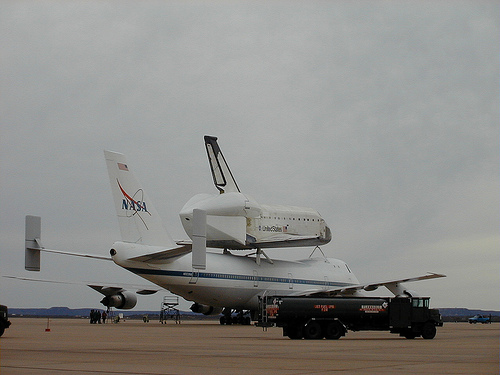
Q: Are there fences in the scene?
A: No, there are no fences.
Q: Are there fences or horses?
A: No, there are no fences or horses.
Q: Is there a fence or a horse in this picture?
A: No, there are no fences or horses.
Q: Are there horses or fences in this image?
A: No, there are no fences or horses.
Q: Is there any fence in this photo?
A: No, there are no fences.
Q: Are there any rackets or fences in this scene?
A: No, there are no fences or rackets.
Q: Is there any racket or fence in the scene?
A: No, there are no fences or rackets.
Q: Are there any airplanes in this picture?
A: Yes, there is an airplane.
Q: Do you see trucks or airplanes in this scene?
A: Yes, there is an airplane.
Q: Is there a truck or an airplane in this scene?
A: Yes, there is an airplane.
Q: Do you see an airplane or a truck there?
A: Yes, there is an airplane.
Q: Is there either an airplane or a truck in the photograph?
A: Yes, there is an airplane.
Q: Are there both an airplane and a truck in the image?
A: Yes, there are both an airplane and a truck.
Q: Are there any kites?
A: No, there are no kites.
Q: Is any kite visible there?
A: No, there are no kites.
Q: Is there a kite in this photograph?
A: No, there are no kites.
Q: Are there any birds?
A: No, there are no birds.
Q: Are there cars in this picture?
A: No, there are no cars.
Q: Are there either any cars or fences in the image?
A: No, there are no cars or fences.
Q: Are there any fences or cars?
A: No, there are no cars or fences.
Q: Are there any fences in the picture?
A: No, there are no fences.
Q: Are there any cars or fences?
A: No, there are no fences or cars.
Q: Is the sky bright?
A: Yes, the sky is bright.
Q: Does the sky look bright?
A: Yes, the sky is bright.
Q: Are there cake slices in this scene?
A: No, there are no cake slices.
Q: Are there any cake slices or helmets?
A: No, there are no cake slices or helmets.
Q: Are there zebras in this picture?
A: No, there are no zebras.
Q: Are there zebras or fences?
A: No, there are no zebras or fences.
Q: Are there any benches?
A: No, there are no benches.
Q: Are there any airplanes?
A: Yes, there is an airplane.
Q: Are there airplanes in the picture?
A: Yes, there is an airplane.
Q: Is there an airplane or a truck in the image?
A: Yes, there is an airplane.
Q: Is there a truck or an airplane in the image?
A: Yes, there is an airplane.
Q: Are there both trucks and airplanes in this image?
A: Yes, there are both an airplane and a truck.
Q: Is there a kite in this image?
A: No, there are no kites.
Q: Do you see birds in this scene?
A: No, there are no birds.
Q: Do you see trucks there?
A: Yes, there is a truck.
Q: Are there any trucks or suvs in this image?
A: Yes, there is a truck.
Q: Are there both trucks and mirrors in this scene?
A: No, there is a truck but no mirrors.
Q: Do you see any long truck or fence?
A: Yes, there is a long truck.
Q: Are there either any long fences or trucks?
A: Yes, there is a long truck.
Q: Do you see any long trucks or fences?
A: Yes, there is a long truck.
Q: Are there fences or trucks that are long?
A: Yes, the truck is long.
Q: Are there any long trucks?
A: Yes, there is a long truck.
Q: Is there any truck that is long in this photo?
A: Yes, there is a long truck.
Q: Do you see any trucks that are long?
A: Yes, there is a long truck.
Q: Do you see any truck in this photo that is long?
A: Yes, there is a truck that is long.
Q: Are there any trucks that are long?
A: Yes, there is a truck that is long.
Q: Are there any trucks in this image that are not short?
A: Yes, there is a long truck.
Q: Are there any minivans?
A: No, there are no minivans.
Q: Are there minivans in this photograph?
A: No, there are no minivans.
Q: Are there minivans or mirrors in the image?
A: No, there are no minivans or mirrors.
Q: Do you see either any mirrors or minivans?
A: No, there are no minivans or mirrors.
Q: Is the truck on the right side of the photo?
A: Yes, the truck is on the right of the image.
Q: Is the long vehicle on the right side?
A: Yes, the truck is on the right of the image.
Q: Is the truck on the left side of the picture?
A: No, the truck is on the right of the image.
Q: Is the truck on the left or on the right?
A: The truck is on the right of the image.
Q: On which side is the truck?
A: The truck is on the right of the image.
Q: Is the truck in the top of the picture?
A: No, the truck is in the bottom of the image.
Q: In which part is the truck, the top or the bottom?
A: The truck is in the bottom of the image.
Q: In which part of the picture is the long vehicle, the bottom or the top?
A: The truck is in the bottom of the image.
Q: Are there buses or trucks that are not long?
A: No, there is a truck but it is long.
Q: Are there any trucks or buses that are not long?
A: No, there is a truck but it is long.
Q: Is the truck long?
A: Yes, the truck is long.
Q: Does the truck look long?
A: Yes, the truck is long.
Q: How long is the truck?
A: The truck is long.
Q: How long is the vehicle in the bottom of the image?
A: The truck is long.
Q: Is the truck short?
A: No, the truck is long.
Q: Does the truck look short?
A: No, the truck is long.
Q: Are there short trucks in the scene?
A: No, there is a truck but it is long.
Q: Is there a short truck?
A: No, there is a truck but it is long.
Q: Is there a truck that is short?
A: No, there is a truck but it is long.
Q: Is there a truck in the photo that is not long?
A: No, there is a truck but it is long.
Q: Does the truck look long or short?
A: The truck is long.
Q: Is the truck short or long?
A: The truck is long.